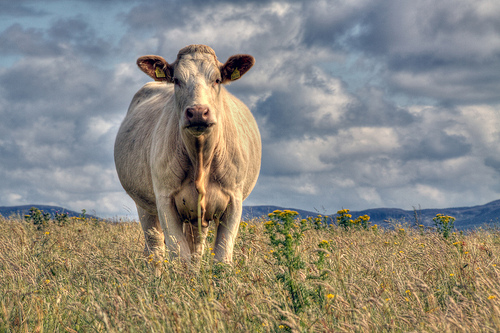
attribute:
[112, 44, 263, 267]
cow — standing, large, tan, white, facing ahead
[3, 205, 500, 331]
field — grassy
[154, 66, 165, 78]
tag — yellow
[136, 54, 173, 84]
ear — dark, large, brown, tagged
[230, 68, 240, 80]
tag — yellow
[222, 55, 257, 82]
ear — dark, large, brown, tagged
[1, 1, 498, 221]
sky — cloudy, grey, gloomy, blue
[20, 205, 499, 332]
flowers — yellow, tall, large, green, weeds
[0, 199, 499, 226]
hill — a slope, blue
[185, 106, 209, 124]
nose — pink, large, brown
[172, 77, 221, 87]
eyes — small, black